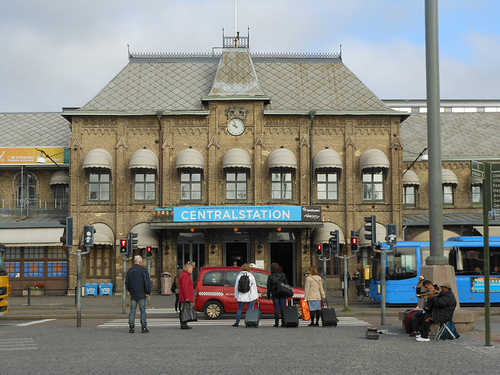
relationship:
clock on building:
[226, 117, 246, 137] [6, 36, 477, 300]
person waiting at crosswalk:
[301, 264, 327, 327] [99, 314, 373, 328]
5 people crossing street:
[120, 250, 345, 328] [16, 270, 465, 305]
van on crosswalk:
[191, 262, 321, 318] [125, 304, 358, 326]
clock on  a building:
[226, 117, 246, 137] [6, 36, 477, 300]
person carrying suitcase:
[232, 263, 261, 327] [243, 303, 262, 325]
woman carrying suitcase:
[264, 263, 299, 324] [280, 304, 301, 324]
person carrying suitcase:
[304, 266, 327, 328] [320, 300, 343, 326]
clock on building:
[220, 113, 245, 138] [6, 36, 477, 300]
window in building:
[125, 147, 164, 204] [6, 36, 477, 300]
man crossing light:
[124, 255, 153, 333] [343, 209, 389, 268]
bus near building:
[375, 240, 483, 270] [100, 73, 480, 216]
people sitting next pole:
[404, 272, 444, 332] [409, 147, 455, 238]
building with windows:
[4, 53, 480, 235] [86, 151, 389, 204]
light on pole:
[361, 210, 390, 247] [379, 260, 393, 309]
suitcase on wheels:
[268, 304, 302, 334] [282, 321, 302, 332]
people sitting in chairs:
[404, 276, 441, 332] [437, 319, 453, 342]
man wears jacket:
[119, 250, 160, 333] [122, 263, 156, 301]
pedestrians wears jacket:
[178, 263, 195, 330] [172, 264, 202, 307]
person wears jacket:
[230, 261, 262, 324] [228, 268, 260, 306]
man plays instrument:
[421, 279, 462, 331] [417, 292, 438, 312]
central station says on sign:
[182, 206, 292, 226] [170, 204, 302, 225]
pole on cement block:
[419, 4, 448, 251] [417, 255, 464, 311]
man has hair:
[124, 255, 153, 333] [133, 250, 140, 262]